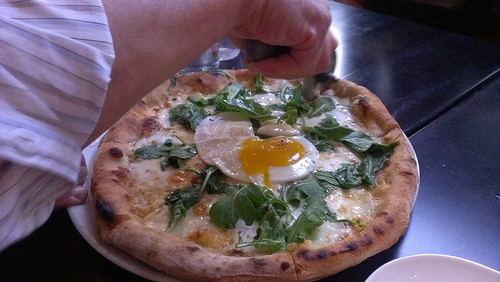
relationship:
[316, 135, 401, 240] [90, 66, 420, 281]
cheese on personal pizza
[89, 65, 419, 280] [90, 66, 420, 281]
crust on personal pizza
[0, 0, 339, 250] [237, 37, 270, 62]
man holding handle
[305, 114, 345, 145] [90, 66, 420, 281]
leaf on personal pizza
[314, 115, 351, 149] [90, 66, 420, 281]
leaf on personal pizza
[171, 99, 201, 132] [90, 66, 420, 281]
leaf on personal pizza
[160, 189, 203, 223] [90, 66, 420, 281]
leaf on personal pizza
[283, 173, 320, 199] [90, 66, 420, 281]
leaf on personal pizza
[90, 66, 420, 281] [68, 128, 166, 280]
personal pizza on plate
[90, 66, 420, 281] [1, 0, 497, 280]
personal pizza on table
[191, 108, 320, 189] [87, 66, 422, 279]
egg on personal pizza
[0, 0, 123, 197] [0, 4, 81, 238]
shirt has pinstripe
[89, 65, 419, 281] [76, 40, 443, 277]
crust on pizza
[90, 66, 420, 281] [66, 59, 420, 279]
personal pizza on plate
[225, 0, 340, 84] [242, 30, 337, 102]
hand holds cutter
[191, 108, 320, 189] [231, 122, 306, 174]
egg has yolk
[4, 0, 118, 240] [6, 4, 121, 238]
material has pinstripe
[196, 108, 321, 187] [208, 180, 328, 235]
egg on spinach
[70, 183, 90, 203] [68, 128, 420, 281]
finger tip on plate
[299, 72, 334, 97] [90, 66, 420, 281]
wheel on personal pizza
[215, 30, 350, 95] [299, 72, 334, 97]
cutter has wheel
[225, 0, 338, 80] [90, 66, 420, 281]
hand by personal pizza